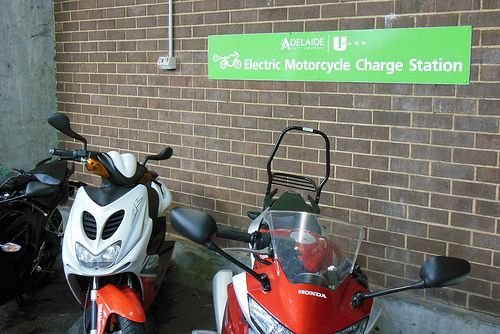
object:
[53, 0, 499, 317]
brick wall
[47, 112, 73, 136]
mirror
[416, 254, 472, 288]
mirrors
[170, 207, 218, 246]
mirrors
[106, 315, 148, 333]
tire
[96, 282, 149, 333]
cover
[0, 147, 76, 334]
motorcycle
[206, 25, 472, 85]
green sign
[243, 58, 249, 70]
white lettering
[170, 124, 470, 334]
motorcycle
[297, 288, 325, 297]
honda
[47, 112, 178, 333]
motorcycle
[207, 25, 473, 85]
sign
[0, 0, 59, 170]
gray wall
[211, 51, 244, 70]
motorcycle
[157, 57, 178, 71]
outlet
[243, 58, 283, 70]
words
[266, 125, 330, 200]
rack